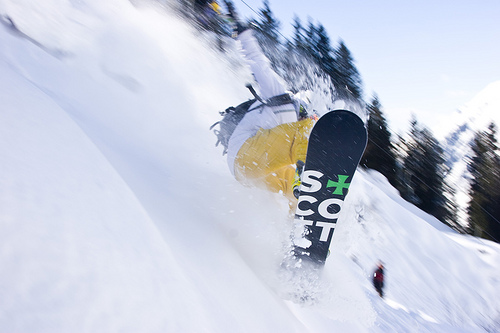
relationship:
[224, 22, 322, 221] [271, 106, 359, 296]
he on snowboard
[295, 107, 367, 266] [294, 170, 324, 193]
board has letters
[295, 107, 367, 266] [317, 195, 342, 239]
board has lettering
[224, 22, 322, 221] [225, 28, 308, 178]
he wearing white jacket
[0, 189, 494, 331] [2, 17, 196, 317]
snow covered ground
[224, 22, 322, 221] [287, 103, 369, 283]
he on snowboard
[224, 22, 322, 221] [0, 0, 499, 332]
he on snow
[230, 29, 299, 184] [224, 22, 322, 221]
white jacket on he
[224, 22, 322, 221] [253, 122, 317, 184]
he wearing pants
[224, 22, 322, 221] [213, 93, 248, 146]
he holds back bag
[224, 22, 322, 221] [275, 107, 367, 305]
he riding board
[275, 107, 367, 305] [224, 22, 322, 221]
board on he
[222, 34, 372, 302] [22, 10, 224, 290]
snowboader on mountain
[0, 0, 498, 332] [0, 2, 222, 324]
mountain covered in snow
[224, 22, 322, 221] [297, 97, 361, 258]
he on snowboard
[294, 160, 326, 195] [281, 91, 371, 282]
letters on snowboard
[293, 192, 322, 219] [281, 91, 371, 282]
letters on snowboard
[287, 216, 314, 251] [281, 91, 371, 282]
letters on snowboard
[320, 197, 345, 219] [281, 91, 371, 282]
letters on snowboard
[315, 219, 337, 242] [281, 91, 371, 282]
letters on snowboard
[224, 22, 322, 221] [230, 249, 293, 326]
he makes tracks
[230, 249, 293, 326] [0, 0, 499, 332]
tracks on mountain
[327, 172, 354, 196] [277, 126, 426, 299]
cross on board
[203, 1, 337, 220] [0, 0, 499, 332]
he in snow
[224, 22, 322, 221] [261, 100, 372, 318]
he riding snowboard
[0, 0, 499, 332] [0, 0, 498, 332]
snow on mountain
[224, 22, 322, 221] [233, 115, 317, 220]
he wearing pants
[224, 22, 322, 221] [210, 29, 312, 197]
he with snowsuit